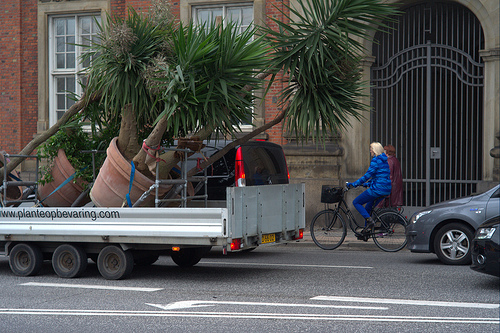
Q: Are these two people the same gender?
A: Yes, all the people are female.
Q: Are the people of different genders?
A: No, all the people are female.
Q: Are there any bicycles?
A: Yes, there is a bicycle.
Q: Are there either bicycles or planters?
A: Yes, there is a bicycle.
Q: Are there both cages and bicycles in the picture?
A: No, there is a bicycle but no cages.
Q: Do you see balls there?
A: No, there are no balls.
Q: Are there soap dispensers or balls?
A: No, there are no balls or soap dispensers.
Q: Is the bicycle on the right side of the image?
A: Yes, the bicycle is on the right of the image.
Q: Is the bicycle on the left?
A: No, the bicycle is on the right of the image.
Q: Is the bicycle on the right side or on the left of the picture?
A: The bicycle is on the right of the image.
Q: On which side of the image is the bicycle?
A: The bicycle is on the right of the image.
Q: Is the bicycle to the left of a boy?
A: No, the bicycle is to the left of the car.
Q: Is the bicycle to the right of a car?
A: No, the bicycle is to the left of a car.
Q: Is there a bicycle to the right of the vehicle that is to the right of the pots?
A: Yes, there is a bicycle to the right of the SUV.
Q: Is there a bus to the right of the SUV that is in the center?
A: No, there is a bicycle to the right of the SUV.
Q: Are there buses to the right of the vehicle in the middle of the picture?
A: No, there is a bicycle to the right of the SUV.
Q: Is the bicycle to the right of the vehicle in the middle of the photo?
A: Yes, the bicycle is to the right of the SUV.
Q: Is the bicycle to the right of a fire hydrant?
A: No, the bicycle is to the right of the SUV.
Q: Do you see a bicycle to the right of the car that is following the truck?
A: No, the bicycle is to the left of the car.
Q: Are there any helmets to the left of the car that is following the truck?
A: No, there is a bicycle to the left of the car.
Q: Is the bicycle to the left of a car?
A: Yes, the bicycle is to the left of a car.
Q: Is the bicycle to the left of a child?
A: No, the bicycle is to the left of a car.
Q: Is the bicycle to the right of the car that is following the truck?
A: No, the bicycle is to the left of the car.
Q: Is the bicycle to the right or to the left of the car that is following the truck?
A: The bicycle is to the left of the car.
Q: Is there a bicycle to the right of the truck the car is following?
A: Yes, there is a bicycle to the right of the truck.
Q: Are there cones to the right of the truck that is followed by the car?
A: No, there is a bicycle to the right of the truck.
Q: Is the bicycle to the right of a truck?
A: Yes, the bicycle is to the right of a truck.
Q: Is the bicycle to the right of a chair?
A: No, the bicycle is to the right of a truck.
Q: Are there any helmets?
A: No, there are no helmets.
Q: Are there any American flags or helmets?
A: No, there are no helmets or American flags.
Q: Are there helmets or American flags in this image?
A: No, there are no helmets or American flags.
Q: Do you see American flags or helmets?
A: No, there are no helmets or American flags.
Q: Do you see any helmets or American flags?
A: No, there are no helmets or American flags.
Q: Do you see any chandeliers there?
A: No, there are no chandeliers.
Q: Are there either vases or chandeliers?
A: No, there are no chandeliers or vases.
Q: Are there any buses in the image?
A: No, there are no buses.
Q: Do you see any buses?
A: No, there are no buses.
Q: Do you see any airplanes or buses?
A: No, there are no buses or airplanes.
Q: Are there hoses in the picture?
A: No, there are no hoses.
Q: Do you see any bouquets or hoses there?
A: No, there are no hoses or bouquets.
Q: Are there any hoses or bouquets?
A: No, there are no hoses or bouquets.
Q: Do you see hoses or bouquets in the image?
A: No, there are no hoses or bouquets.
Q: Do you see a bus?
A: No, there are no buses.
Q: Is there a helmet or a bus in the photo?
A: No, there are no buses or helmets.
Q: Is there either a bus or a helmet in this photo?
A: No, there are no buses or helmets.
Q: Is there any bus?
A: No, there are no buses.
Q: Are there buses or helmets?
A: No, there are no buses or helmets.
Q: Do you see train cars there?
A: No, there are no train cars.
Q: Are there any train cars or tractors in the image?
A: No, there are no train cars or tractors.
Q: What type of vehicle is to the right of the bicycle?
A: The vehicle is a car.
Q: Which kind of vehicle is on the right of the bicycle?
A: The vehicle is a car.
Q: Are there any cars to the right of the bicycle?
A: Yes, there is a car to the right of the bicycle.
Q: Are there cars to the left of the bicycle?
A: No, the car is to the right of the bicycle.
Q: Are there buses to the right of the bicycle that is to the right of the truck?
A: No, there is a car to the right of the bicycle.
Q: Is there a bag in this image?
A: Yes, there is a bag.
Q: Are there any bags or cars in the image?
A: Yes, there is a bag.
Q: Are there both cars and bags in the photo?
A: Yes, there are both a bag and a car.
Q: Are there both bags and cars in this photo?
A: Yes, there are both a bag and a car.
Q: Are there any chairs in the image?
A: No, there are no chairs.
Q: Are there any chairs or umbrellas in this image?
A: No, there are no chairs or umbrellas.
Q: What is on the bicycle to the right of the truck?
A: The bag is on the bicycle.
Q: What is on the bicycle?
A: The bag is on the bicycle.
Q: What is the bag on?
A: The bag is on the bicycle.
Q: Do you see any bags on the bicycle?
A: Yes, there is a bag on the bicycle.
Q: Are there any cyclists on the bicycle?
A: No, there is a bag on the bicycle.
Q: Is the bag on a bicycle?
A: Yes, the bag is on a bicycle.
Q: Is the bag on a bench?
A: No, the bag is on a bicycle.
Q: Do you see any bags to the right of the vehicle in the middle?
A: Yes, there is a bag to the right of the SUV.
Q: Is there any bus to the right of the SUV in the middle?
A: No, there is a bag to the right of the SUV.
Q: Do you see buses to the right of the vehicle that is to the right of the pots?
A: No, there is a bag to the right of the SUV.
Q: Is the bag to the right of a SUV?
A: Yes, the bag is to the right of a SUV.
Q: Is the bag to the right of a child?
A: No, the bag is to the right of a SUV.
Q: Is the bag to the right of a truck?
A: Yes, the bag is to the right of a truck.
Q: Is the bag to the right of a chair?
A: No, the bag is to the right of a truck.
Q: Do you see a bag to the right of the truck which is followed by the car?
A: Yes, there is a bag to the right of the truck.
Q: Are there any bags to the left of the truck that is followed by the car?
A: No, the bag is to the right of the truck.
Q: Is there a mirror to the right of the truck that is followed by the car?
A: No, there is a bag to the right of the truck.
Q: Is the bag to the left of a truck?
A: No, the bag is to the right of a truck.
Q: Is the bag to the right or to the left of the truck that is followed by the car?
A: The bag is to the right of the truck.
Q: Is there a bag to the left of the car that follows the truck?
A: Yes, there is a bag to the left of the car.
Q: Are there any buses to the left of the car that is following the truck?
A: No, there is a bag to the left of the car.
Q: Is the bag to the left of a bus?
A: No, the bag is to the left of the car.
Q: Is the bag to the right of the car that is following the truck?
A: No, the bag is to the left of the car.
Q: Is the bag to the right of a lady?
A: No, the bag is to the left of a lady.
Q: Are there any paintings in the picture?
A: No, there are no paintings.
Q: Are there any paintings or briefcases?
A: No, there are no paintings or briefcases.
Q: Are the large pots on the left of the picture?
A: Yes, the pots are on the left of the image.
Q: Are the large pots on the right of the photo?
A: No, the pots are on the left of the image.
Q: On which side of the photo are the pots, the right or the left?
A: The pots are on the left of the image.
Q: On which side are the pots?
A: The pots are on the left of the image.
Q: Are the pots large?
A: Yes, the pots are large.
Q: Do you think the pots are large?
A: Yes, the pots are large.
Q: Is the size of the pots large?
A: Yes, the pots are large.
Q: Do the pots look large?
A: Yes, the pots are large.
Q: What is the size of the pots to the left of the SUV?
A: The pots are large.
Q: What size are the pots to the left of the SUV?
A: The pots are large.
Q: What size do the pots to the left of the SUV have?
A: The pots have large size.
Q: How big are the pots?
A: The pots are large.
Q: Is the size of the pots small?
A: No, the pots are large.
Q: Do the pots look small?
A: No, the pots are large.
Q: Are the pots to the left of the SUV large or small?
A: The pots are large.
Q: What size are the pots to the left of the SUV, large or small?
A: The pots are large.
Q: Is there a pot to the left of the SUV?
A: Yes, there are pots to the left of the SUV.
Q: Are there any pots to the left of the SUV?
A: Yes, there are pots to the left of the SUV.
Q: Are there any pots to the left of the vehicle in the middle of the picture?
A: Yes, there are pots to the left of the SUV.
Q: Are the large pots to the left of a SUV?
A: Yes, the pots are to the left of a SUV.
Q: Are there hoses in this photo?
A: No, there are no hoses.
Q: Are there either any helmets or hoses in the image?
A: No, there are no hoses or helmets.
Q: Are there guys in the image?
A: No, there are no guys.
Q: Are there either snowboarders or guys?
A: No, there are no guys or snowboarders.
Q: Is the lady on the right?
A: Yes, the lady is on the right of the image.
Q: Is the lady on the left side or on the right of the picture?
A: The lady is on the right of the image.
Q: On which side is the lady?
A: The lady is on the right of the image.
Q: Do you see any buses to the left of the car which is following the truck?
A: No, there is a lady to the left of the car.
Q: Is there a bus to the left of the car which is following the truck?
A: No, there is a lady to the left of the car.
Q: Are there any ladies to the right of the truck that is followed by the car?
A: Yes, there is a lady to the right of the truck.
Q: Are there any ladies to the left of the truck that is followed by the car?
A: No, the lady is to the right of the truck.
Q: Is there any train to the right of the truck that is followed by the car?
A: No, there is a lady to the right of the truck.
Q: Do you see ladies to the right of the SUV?
A: Yes, there is a lady to the right of the SUV.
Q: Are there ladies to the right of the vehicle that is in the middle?
A: Yes, there is a lady to the right of the SUV.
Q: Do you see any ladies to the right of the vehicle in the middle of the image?
A: Yes, there is a lady to the right of the SUV.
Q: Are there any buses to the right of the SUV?
A: No, there is a lady to the right of the SUV.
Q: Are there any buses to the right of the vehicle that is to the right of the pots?
A: No, there is a lady to the right of the SUV.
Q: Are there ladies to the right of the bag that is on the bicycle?
A: Yes, there is a lady to the right of the bag.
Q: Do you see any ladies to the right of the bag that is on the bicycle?
A: Yes, there is a lady to the right of the bag.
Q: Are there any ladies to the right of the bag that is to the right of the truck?
A: Yes, there is a lady to the right of the bag.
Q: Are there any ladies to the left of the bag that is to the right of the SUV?
A: No, the lady is to the right of the bag.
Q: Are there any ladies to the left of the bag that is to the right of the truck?
A: No, the lady is to the right of the bag.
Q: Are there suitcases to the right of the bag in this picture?
A: No, there is a lady to the right of the bag.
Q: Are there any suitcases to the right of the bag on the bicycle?
A: No, there is a lady to the right of the bag.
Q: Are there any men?
A: No, there are no men.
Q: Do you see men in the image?
A: No, there are no men.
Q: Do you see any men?
A: No, there are no men.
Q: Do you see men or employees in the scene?
A: No, there are no men or employees.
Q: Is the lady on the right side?
A: Yes, the lady is on the right of the image.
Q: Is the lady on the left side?
A: No, the lady is on the right of the image.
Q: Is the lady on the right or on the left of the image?
A: The lady is on the right of the image.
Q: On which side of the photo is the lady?
A: The lady is on the right of the image.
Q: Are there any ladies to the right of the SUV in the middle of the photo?
A: Yes, there is a lady to the right of the SUV.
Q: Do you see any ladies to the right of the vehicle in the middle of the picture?
A: Yes, there is a lady to the right of the SUV.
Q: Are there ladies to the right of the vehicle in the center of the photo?
A: Yes, there is a lady to the right of the SUV.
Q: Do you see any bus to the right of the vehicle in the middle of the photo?
A: No, there is a lady to the right of the SUV.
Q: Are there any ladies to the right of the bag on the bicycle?
A: Yes, there is a lady to the right of the bag.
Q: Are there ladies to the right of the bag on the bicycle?
A: Yes, there is a lady to the right of the bag.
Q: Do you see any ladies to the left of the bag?
A: No, the lady is to the right of the bag.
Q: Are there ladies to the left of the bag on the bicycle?
A: No, the lady is to the right of the bag.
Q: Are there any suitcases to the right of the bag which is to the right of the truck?
A: No, there is a lady to the right of the bag.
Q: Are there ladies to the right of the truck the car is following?
A: Yes, there is a lady to the right of the truck.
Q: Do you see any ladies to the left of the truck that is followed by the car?
A: No, the lady is to the right of the truck.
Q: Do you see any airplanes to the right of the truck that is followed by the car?
A: No, there is a lady to the right of the truck.